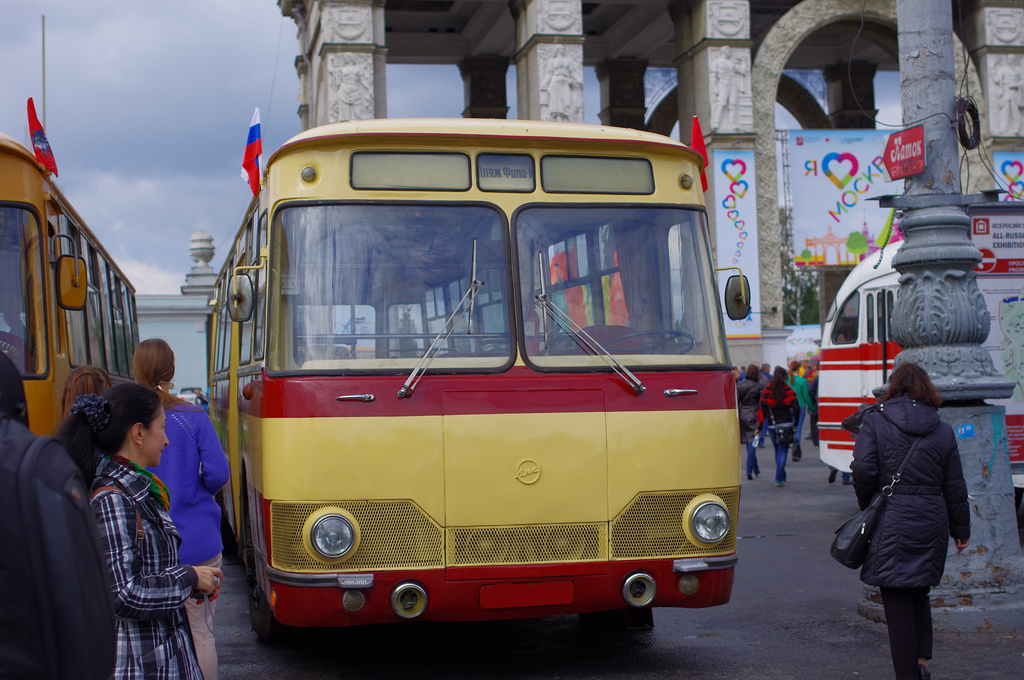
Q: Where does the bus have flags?
A: On each side of the top.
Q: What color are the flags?
A: White,blue and red.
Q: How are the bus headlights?
A: Round.